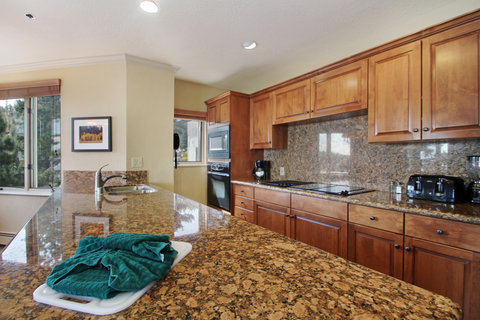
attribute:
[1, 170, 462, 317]
counter — ISLAND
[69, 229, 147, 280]
towel — GREEN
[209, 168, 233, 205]
oven — WALL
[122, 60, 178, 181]
wall — CREAM